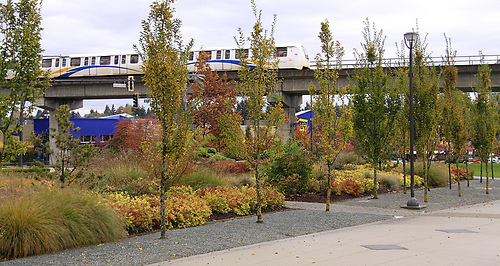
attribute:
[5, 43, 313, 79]
train — long, elevated, white, overhead, passanger-train, large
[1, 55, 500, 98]
bridge — concrete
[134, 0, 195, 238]
tree — green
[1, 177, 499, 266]
sidewalk — paved, graveled, concrete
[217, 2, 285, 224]
tree — small, lined-up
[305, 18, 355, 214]
tree — smal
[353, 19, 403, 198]
tree — green, decorative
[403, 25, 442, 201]
tree — small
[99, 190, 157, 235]
bush — yellow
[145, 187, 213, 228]
bush — beautiful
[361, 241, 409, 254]
manhole — square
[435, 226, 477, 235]
manhole — square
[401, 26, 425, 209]
lightpost — tall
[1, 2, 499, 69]
sky — cloudy, blue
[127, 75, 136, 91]
traffic-light — yellow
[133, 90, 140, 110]
traffic-light — black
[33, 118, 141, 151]
building — blue